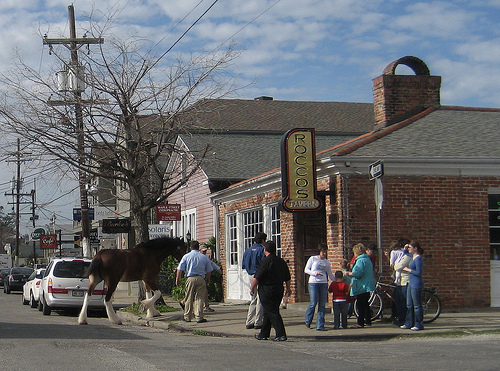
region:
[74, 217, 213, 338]
dark brown horse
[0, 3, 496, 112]
sky is partly cloudy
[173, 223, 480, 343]
people standing at the street corner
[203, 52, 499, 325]
small brick building in the front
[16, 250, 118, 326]
two white cars parked at the curb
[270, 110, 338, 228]
Brick building is Rocco's Tavern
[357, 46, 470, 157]
brick building has a brick chimney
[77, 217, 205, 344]
horse is stepping onto the sidewalk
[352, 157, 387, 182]
one-way sign points opposite of the camera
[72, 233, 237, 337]
lower legs of the horse are white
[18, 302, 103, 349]
shadow cast on the street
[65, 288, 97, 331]
white part of horse's foot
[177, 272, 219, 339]
man wearing brown pants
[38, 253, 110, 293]
black horse's tail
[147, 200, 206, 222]
red and white sign on building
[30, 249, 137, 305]
white suv parked on side of road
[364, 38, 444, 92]
circular top on brown roof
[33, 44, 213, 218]
large bare tree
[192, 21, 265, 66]
white fluffy clouds in the sky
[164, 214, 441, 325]
people walking on the side walk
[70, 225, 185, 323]
Horse in the street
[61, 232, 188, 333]
Horse body is brown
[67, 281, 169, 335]
Horse legs are white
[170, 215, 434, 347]
Group of people in the corner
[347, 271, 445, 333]
Bike is parked behind people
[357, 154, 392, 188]
Street sign with white arrow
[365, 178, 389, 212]
Street sign on a pole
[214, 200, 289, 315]
Door of building is white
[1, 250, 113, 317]
Cars parked on side of street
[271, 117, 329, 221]
Advertising sign is yellow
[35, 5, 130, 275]
an old weathered power pole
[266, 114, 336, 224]
a sign for roccos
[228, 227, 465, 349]
people on a street corner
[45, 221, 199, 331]
a large Clydesdale horse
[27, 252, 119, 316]
a white can on the street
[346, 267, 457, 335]
a white racing bike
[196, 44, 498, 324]
a large brick building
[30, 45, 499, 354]
people in front of a restaurant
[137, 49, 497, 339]
people at a pub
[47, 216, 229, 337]
a man walking a horse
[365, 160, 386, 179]
one way street sign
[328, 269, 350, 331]
boy in red shirt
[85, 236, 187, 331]
horse on the sidewalk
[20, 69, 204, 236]
tree without leaves on it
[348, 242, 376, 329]
woman in blue winter coat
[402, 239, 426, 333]
woman in blue shirt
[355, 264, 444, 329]
bicycle standing against the pole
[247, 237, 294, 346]
man dressed all in black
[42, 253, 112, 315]
white van parked curbside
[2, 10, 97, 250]
three telephone poles